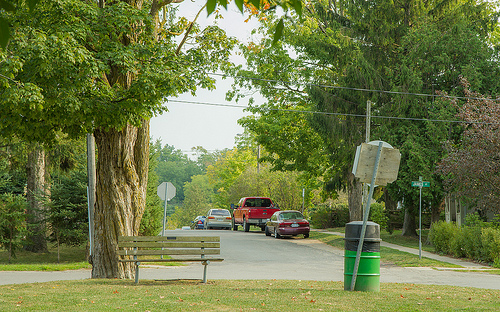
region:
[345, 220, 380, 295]
a green and black trash can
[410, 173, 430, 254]
a green street name sign at the corner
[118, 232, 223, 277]
a wooden bench in a park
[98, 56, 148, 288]
a large tree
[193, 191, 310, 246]
a row of cars on the side of the road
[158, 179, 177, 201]
the back of a stop sign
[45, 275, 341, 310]
a large patch of grassy area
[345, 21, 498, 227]
a bunch of large trees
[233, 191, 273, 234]
a red truck parked in a row of cars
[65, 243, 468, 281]
a T shaped street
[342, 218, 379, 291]
Black and green garbage can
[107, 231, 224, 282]
Wood bench on side of road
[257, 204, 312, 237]
Red car parked in back or orange truck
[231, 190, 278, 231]
Orange truck in front of red car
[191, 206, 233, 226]
Light tan suv in front of orange truck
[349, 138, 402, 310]
Traffic street sign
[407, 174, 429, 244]
Street sign with street name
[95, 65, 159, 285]
Trunk of tall tree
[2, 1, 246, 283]
Tall tree on side of road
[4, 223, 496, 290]
Concret road for automobile traffic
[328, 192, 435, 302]
a green and black garbage can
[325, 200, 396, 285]
green and black trash can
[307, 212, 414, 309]
green and black trash can on grass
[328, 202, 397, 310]
trash can on grass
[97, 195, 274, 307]
a bench in the grass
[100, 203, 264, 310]
a bench next to the road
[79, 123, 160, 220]
a thick tree trunk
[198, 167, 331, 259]
cars parked on the road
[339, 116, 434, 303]
a sign behind the garbage can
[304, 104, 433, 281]
a sign behind the trash can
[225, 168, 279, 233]
a red truck parked in front of a red car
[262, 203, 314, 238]
a red car parked behind a red truck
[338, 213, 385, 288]
a green garbage can in front of a stop sign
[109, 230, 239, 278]
a wooden bench in front of a tree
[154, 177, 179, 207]
a stop sign facing the opposite direction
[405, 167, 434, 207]
a green street sign on the corner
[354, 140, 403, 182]
a board behind the stop sign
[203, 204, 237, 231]
a car in front of a red truck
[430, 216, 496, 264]
some bushes next to a purple tree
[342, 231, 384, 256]
a black garbage bag in a green garbage can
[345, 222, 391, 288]
a green trash can on a corner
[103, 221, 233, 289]
a wood bench on the edge of the grass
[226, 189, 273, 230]
red truck parked on the side of the road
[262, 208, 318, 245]
purple car parked on the side of the road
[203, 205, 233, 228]
green car parked on the side of the road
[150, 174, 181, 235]
back of a stop sign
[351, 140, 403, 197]
back of a stop sign with a wood plank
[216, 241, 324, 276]
grey asphalt of the road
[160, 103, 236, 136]
grey cloudy skies over the road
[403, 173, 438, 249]
green street sign on the corner